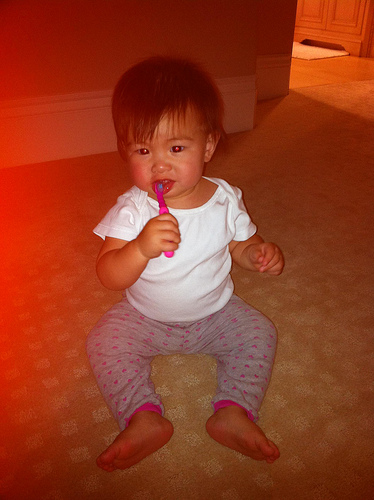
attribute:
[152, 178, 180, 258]
toothbrush — pink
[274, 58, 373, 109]
flooring — brown, wooden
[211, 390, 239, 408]
lining — white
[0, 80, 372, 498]
carpet — white, rectangle pattern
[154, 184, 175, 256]
babyspoon — pink, plastic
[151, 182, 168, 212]
toothbrush — orange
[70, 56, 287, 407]
perosn — gray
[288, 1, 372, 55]
cabinet — two door, wooden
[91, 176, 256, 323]
shirt —   white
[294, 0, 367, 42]
wooddoor — wooden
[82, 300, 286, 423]
pants — red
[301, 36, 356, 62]
rug — wooly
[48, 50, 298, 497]
toddler — young, Asian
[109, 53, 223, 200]
hair — brown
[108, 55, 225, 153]
hair — thin, short, black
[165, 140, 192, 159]
child's eye — red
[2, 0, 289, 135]
wall — whit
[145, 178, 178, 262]
spoon — plastic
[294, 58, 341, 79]
floor — wood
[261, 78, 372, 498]
floor —  White,  carpeted